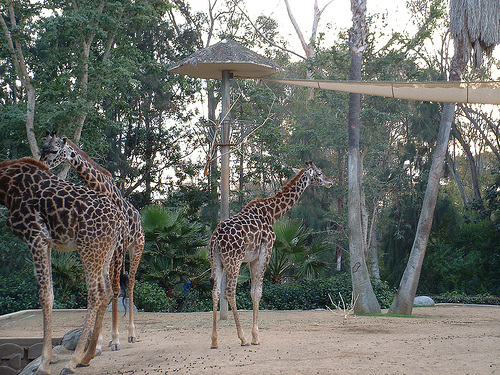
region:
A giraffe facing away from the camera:
[206, 160, 338, 362]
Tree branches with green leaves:
[40, 40, 162, 89]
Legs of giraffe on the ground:
[197, 300, 279, 362]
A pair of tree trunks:
[336, 232, 441, 329]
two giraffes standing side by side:
[0, 118, 158, 373]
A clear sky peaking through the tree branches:
[156, 92, 227, 199]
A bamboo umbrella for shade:
[172, 40, 281, 95]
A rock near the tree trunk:
[410, 291, 438, 315]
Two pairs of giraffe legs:
[29, 287, 167, 373]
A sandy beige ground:
[289, 323, 440, 364]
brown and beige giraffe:
[171, 159, 349, 350]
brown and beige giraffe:
[11, 163, 141, 320]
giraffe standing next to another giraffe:
[40, 131, 156, 188]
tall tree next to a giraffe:
[329, 16, 386, 332]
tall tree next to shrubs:
[395, 34, 487, 305]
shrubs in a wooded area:
[436, 186, 485, 302]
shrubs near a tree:
[285, 211, 343, 313]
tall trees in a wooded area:
[54, 34, 167, 119]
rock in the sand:
[416, 287, 453, 309]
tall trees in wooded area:
[58, 13, 173, 114]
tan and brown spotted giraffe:
[9, 156, 124, 362]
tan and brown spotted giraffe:
[197, 147, 334, 345]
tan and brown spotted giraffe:
[37, 142, 92, 169]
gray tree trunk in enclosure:
[336, 28, 387, 303]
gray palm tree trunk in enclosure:
[403, 8, 493, 222]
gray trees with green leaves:
[14, 6, 151, 123]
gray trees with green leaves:
[277, 43, 417, 153]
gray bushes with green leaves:
[142, 196, 207, 298]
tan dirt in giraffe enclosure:
[284, 326, 484, 361]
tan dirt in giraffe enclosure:
[139, 316, 186, 367]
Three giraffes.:
[25, 130, 323, 276]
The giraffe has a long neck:
[258, 175, 311, 204]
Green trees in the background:
[63, 30, 244, 127]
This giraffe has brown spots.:
[72, 182, 111, 249]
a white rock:
[419, 292, 434, 315]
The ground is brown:
[268, 325, 402, 364]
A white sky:
[383, 10, 407, 27]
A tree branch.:
[237, 20, 270, 46]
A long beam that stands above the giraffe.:
[210, 70, 240, 200]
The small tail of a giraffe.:
[117, 217, 129, 263]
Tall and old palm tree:
[398, 0, 496, 303]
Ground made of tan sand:
[275, 312, 423, 369]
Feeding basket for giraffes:
[182, 111, 269, 149]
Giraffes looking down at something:
[2, 124, 154, 374]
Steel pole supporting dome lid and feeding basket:
[219, 72, 236, 217]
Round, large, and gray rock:
[413, 293, 435, 310]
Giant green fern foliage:
[142, 200, 208, 312]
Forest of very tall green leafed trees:
[5, 63, 161, 138]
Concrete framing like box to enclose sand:
[3, 310, 94, 345]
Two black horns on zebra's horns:
[303, 155, 313, 167]